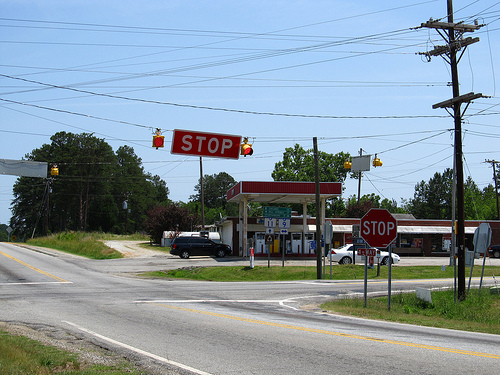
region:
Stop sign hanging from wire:
[173, 127, 240, 166]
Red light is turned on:
[139, 124, 166, 154]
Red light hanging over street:
[238, 136, 261, 160]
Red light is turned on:
[238, 130, 263, 161]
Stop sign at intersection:
[349, 202, 424, 250]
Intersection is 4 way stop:
[347, 245, 384, 260]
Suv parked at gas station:
[165, 227, 235, 260]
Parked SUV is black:
[163, 228, 235, 268]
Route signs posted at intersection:
[260, 216, 302, 240]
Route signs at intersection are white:
[254, 212, 299, 241]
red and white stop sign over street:
[170, 109, 252, 174]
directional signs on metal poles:
[258, 200, 296, 258]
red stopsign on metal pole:
[353, 184, 423, 324]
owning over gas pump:
[216, 154, 343, 276]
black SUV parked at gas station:
[166, 220, 254, 290]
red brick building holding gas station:
[221, 195, 498, 259]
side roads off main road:
[1, 249, 363, 367]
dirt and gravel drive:
[102, 227, 156, 284]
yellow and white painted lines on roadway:
[181, 275, 344, 372]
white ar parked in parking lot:
[329, 225, 417, 277]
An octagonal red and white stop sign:
[358, 206, 396, 248]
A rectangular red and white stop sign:
[169, 128, 241, 160]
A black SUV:
[170, 235, 233, 258]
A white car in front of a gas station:
[329, 243, 399, 265]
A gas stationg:
[217, 218, 497, 258]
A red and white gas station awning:
[225, 180, 341, 260]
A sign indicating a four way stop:
[355, 247, 375, 256]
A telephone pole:
[414, 0, 484, 298]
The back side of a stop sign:
[465, 222, 490, 289]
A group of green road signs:
[261, 204, 292, 217]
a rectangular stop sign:
[172, 128, 245, 165]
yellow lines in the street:
[5, 254, 42, 274]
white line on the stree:
[69, 318, 126, 354]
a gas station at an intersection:
[167, 154, 454, 274]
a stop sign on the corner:
[357, 207, 405, 306]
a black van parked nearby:
[161, 229, 223, 264]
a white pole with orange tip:
[240, 248, 260, 275]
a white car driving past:
[331, 237, 389, 262]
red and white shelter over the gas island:
[221, 176, 349, 201]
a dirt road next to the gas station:
[119, 233, 157, 260]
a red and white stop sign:
[362, 207, 399, 249]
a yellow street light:
[148, 127, 168, 151]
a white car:
[328, 239, 398, 266]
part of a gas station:
[227, 180, 346, 260]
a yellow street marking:
[155, 302, 497, 370]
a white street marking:
[58, 315, 208, 374]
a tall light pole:
[422, 0, 489, 308]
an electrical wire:
[2, 74, 499, 124]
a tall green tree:
[11, 129, 126, 241]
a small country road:
[102, 231, 165, 258]